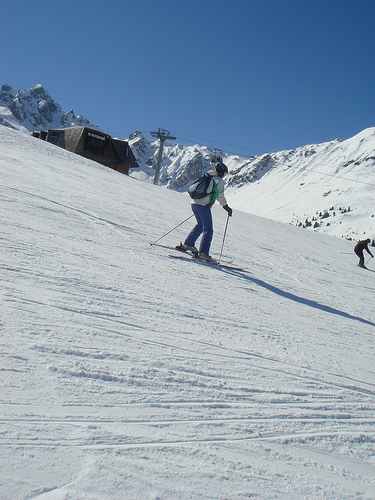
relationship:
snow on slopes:
[11, 146, 375, 494] [167, 147, 374, 246]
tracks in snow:
[19, 386, 375, 459] [11, 146, 375, 494]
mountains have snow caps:
[2, 85, 264, 187] [3, 80, 65, 107]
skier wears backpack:
[185, 159, 233, 267] [189, 170, 212, 202]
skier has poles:
[185, 159, 233, 267] [147, 207, 229, 268]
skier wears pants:
[185, 159, 233, 267] [185, 199, 209, 255]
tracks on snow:
[19, 386, 375, 459] [11, 146, 375, 494]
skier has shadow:
[185, 159, 233, 267] [209, 258, 373, 327]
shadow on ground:
[209, 258, 373, 327] [0, 245, 370, 496]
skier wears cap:
[185, 159, 233, 267] [217, 162, 227, 174]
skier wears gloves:
[185, 159, 233, 267] [222, 203, 234, 215]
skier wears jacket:
[185, 159, 233, 267] [188, 168, 226, 204]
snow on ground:
[11, 146, 375, 494] [0, 245, 370, 496]